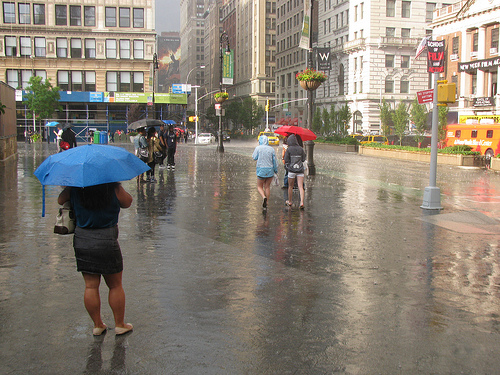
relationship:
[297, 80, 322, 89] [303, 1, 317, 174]
basket hangs on pole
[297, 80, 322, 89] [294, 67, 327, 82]
basket of flower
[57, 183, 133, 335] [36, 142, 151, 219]
woman carries umbrella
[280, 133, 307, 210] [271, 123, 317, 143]
girl follows umbrella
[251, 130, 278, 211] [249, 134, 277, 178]
girl wears jacket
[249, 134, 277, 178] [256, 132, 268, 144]
jacket has hood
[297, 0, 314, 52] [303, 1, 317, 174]
banner on pole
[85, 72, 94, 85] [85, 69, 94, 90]
shade on window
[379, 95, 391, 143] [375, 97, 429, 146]
tree in line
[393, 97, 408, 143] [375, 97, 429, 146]
tree in line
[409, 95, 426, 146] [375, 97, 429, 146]
tree in line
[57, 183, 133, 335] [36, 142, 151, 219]
woman carrying umbrella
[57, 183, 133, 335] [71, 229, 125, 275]
woman wearing skirt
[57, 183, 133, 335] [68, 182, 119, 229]
woman wearing shirt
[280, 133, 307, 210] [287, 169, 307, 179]
girl in shorts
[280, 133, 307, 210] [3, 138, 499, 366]
girl on sidewalk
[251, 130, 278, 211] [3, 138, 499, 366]
girl on sidewalk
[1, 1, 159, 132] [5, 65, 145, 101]
building with row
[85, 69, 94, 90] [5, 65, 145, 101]
window in row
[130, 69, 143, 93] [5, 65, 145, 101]
window in row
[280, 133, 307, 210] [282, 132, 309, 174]
girl wearing sweatshirt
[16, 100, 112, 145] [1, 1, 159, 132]
scaffolding under building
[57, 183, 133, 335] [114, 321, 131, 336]
woman wearing shoe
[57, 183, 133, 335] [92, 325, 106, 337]
woman wearing shoe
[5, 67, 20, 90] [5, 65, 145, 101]
window in row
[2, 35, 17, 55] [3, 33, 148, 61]
window in row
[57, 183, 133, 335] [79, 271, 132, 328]
woman has skin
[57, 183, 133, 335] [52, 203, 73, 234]
woman carrying handbag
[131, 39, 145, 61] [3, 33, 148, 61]
window in row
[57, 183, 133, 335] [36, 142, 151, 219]
woman under umbrella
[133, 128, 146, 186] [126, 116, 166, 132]
man under umbrella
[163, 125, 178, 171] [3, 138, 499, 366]
person on sidewalk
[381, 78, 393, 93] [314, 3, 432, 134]
window on building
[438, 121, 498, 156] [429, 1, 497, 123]
truck in front of building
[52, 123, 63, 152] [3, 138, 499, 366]
person on sidewalk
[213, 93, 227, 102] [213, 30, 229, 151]
basket on pole